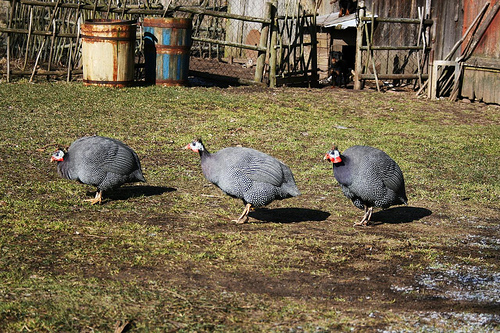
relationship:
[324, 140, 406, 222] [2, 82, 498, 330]
guinea hen are in grass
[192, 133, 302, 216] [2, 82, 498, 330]
guinea hen are in grass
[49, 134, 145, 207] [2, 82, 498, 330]
guinea hen are in grass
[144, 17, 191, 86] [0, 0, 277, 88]
trash against fence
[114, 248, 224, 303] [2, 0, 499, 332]
ground in turkey farm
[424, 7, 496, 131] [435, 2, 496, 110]
wood leaning against building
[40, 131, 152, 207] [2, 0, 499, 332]
bird on turkey farm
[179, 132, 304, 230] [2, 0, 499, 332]
bird on turkey farm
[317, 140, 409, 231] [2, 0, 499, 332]
bird on turkey farm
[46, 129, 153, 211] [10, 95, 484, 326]
turkeys walking on grass